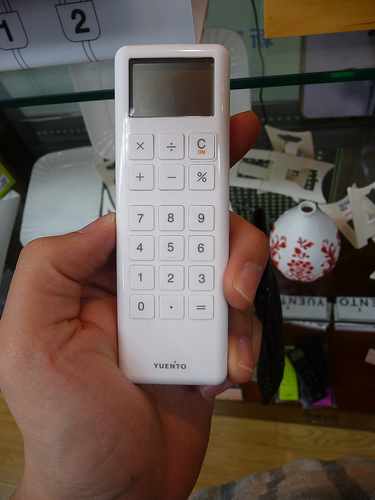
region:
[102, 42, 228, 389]
white oblong calculator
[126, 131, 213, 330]
buttons on the calculator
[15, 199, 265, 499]
hand holding the calculator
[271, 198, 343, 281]
white and red vase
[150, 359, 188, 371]
gray lettering on white background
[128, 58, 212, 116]
screen of the calculator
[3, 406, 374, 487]
hardwood flooring in the room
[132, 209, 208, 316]
gray numbers on white background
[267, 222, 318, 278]
red leaf print on the white vase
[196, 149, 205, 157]
red lettering on white background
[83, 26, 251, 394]
a white Yuento calculator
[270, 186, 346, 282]
a white vase with red design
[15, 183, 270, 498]
a calculator in hand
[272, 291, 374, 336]
white paper with black letters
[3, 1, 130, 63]
a white paper with black numbers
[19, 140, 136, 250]
a square white plate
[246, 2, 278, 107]
a black cord running down wall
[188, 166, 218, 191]
a percent sign on calculator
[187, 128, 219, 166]
the On button of calculator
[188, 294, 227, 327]
an equal sign on calculator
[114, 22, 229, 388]
the device is white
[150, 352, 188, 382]
the text is gray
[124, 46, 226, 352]
the calculator is long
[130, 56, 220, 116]
the screen is off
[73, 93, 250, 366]
holding an odd calculator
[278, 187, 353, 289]
the vase is white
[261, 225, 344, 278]
the floral patterns are red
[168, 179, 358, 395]
the desk is black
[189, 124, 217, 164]
this is the on button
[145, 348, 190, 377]
the text says yuento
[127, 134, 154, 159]
button on white remote control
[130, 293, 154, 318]
button on white remote control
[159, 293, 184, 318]
button on white remote control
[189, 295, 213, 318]
button on white remote control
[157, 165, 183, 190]
button on white remote control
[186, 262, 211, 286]
button on white remote control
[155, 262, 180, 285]
button on white remote control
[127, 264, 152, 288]
button on white remote control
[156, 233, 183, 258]
button on white remote control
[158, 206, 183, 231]
button on white remote control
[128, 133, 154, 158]
white button on remote control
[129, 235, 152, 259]
white button on remote control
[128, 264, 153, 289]
white button on remote control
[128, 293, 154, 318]
white button on remote control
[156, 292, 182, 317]
white button on remote control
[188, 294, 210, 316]
white button on remote control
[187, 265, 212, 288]
white button on remote control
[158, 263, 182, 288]
white button on remote control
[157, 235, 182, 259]
white button on remote control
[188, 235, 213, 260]
white button on remote control